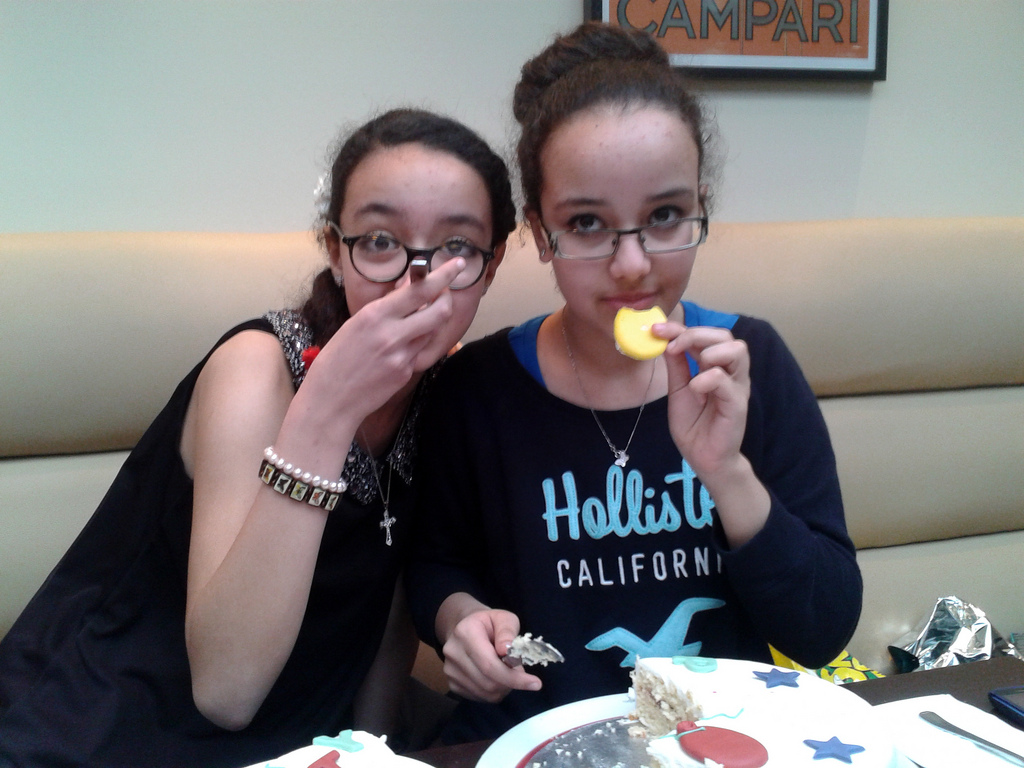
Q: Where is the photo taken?
A: At a restaurant.